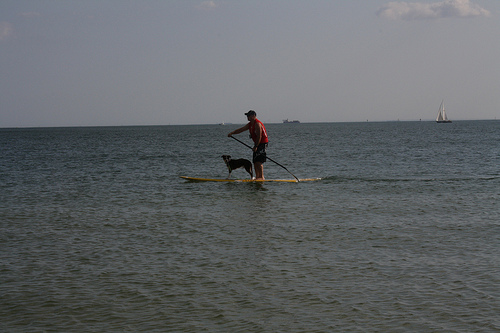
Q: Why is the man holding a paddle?
A: So he can row the board.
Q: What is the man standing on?
A: A board.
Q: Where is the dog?
A: By the man.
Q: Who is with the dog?
A: The man.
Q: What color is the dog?
A: Black.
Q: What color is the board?
A: Yellow.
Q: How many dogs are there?
A: 1.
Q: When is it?
A: Day time.